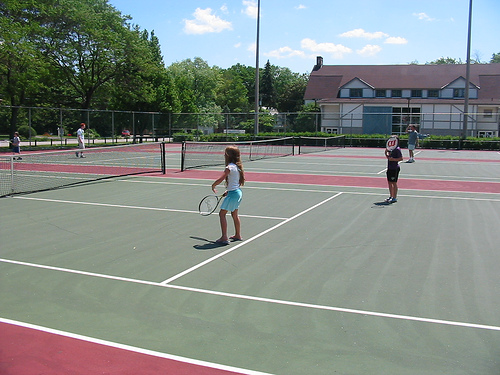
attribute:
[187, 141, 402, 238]
people — young, playing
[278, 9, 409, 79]
clouds — white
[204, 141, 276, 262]
girl — young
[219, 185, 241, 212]
pants — blue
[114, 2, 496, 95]
sky — blue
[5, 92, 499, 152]
fence — chain link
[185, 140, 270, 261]
girl — young, holding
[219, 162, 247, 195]
shirt — white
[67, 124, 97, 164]
payer — dressed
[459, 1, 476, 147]
pole — tall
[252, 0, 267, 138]
pole — tall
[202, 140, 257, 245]
girl — young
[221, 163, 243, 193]
shirt — white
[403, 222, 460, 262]
turf — green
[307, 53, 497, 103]
roof — red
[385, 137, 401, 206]
player — dressed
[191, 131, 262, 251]
girl — young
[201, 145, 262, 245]
girl — young, dressed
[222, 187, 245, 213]
shorts — blue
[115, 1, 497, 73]
sky — blue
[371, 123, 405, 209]
girl — wearing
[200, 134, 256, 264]
girl — young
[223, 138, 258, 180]
hair — blonde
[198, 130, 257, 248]
player — holding